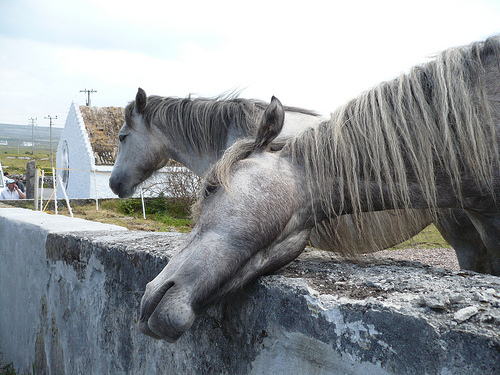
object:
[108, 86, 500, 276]
horse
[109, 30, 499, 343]
horses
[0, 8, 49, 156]
outside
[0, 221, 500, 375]
wall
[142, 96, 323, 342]
head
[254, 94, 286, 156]
ear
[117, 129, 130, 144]
eye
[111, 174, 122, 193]
nose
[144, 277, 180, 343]
mouth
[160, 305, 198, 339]
chin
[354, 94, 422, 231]
mane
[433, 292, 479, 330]
chips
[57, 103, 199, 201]
building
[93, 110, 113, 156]
brown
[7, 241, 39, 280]
grey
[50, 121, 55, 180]
wooden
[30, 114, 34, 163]
pole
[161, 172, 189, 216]
shrubs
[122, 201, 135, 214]
bush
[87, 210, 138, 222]
road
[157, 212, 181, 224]
grass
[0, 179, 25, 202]
man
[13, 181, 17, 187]
phone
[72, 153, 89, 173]
white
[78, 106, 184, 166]
roof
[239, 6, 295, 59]
clouds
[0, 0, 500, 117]
sky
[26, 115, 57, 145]
poles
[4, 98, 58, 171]
distance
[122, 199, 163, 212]
bushes